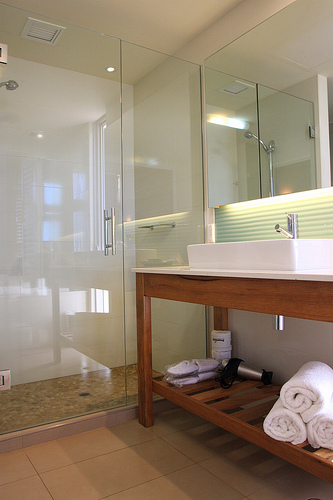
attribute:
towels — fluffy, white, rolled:
[266, 369, 331, 447]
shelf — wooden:
[179, 404, 319, 472]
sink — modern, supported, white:
[202, 236, 316, 261]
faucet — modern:
[268, 216, 302, 241]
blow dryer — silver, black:
[222, 354, 271, 385]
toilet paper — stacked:
[203, 324, 235, 364]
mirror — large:
[209, 63, 330, 183]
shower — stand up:
[13, 70, 120, 354]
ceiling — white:
[8, 9, 201, 74]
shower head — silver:
[243, 123, 278, 152]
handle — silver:
[104, 210, 120, 255]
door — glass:
[91, 161, 131, 321]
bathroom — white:
[27, 65, 325, 405]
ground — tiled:
[31, 435, 225, 499]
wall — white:
[24, 86, 110, 253]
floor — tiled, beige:
[42, 447, 324, 495]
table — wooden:
[148, 267, 331, 292]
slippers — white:
[170, 354, 217, 383]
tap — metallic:
[276, 224, 288, 237]